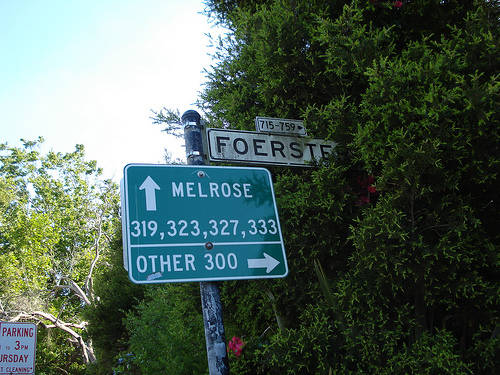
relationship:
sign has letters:
[119, 160, 295, 294] [171, 177, 255, 197]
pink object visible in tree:
[227, 334, 243, 358] [156, 5, 498, 373]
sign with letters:
[206, 107, 357, 172] [216, 132, 330, 159]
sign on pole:
[119, 160, 295, 294] [181, 109, 229, 374]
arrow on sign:
[132, 170, 160, 214] [119, 160, 295, 294]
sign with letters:
[119, 160, 295, 294] [171, 180, 186, 200]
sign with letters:
[119, 160, 295, 294] [185, 181, 195, 198]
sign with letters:
[119, 160, 295, 294] [196, 180, 210, 198]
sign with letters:
[119, 160, 295, 294] [207, 181, 221, 198]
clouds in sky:
[80, 49, 155, 154] [7, 5, 121, 77]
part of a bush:
[460, 189, 480, 207] [274, 4, 497, 316]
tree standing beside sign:
[1, 139, 126, 364] [203, 127, 341, 164]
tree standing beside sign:
[1, 139, 126, 364] [256, 112, 307, 136]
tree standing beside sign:
[1, 139, 126, 364] [121, 157, 288, 288]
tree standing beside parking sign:
[1, 139, 126, 364] [0, 322, 36, 371]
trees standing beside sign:
[116, 2, 497, 374] [119, 160, 295, 294]